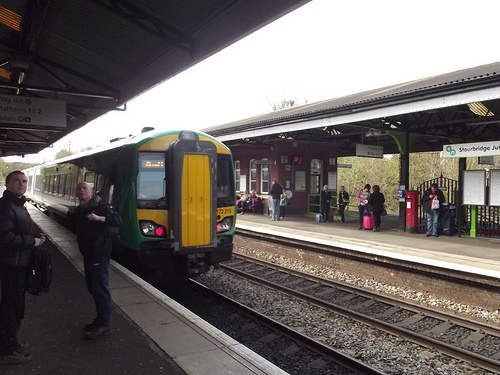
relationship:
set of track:
[131, 284, 491, 370] [196, 265, 498, 373]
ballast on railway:
[193, 245, 499, 374] [185, 251, 498, 372]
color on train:
[183, 154, 211, 243] [11, 121, 242, 280]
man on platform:
[64, 182, 123, 339] [1, 200, 268, 374]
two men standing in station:
[1, 169, 124, 363] [1, 5, 493, 372]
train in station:
[11, 121, 242, 280] [1, 5, 493, 372]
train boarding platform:
[11, 126, 242, 280] [19, 199, 293, 374]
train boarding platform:
[11, 126, 242, 280] [234, 207, 499, 282]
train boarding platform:
[11, 126, 242, 280] [232, 210, 498, 295]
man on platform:
[65, 179, 118, 342] [1, 192, 296, 372]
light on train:
[132, 220, 157, 243] [15, 114, 258, 288]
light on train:
[221, 218, 236, 236] [15, 114, 258, 288]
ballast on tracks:
[193, 245, 499, 374] [154, 226, 499, 373]